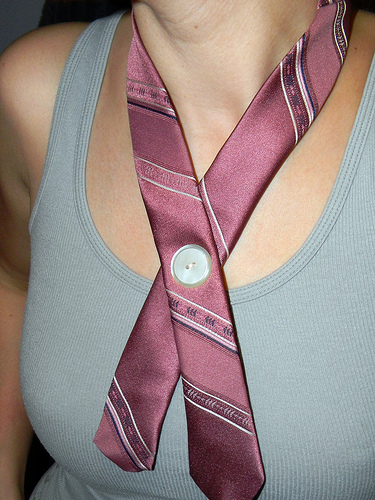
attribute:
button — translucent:
[160, 235, 216, 293]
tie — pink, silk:
[111, 12, 365, 412]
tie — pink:
[96, 3, 359, 498]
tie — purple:
[173, 155, 248, 185]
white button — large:
[168, 240, 207, 288]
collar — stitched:
[75, 11, 374, 307]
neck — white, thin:
[128, 2, 345, 50]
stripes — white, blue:
[271, 35, 328, 133]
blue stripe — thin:
[105, 402, 143, 470]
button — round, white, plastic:
[174, 242, 204, 283]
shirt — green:
[11, 12, 373, 497]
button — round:
[171, 243, 212, 285]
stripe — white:
[111, 370, 153, 458]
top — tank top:
[55, 22, 366, 445]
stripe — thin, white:
[183, 395, 253, 437]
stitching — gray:
[72, 12, 374, 307]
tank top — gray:
[17, 10, 374, 498]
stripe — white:
[126, 76, 166, 93]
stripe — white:
[127, 93, 174, 113]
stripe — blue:
[128, 99, 177, 119]